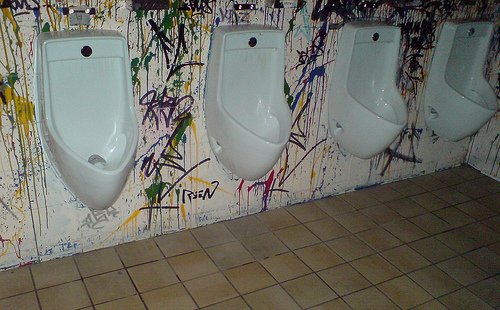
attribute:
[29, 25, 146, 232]
bathroom urinal — white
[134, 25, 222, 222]
graffiti — colorful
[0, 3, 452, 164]
bathroom walls — vandalized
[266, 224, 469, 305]
tile floor — beige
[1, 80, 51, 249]
smearing paint — yellow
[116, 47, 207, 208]
scribble — black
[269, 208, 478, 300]
shapes — square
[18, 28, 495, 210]
urinals — four  white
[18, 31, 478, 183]
wall — dirty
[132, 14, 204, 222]
paint — green dripping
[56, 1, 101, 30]
sheet — metal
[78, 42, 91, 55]
circle — metal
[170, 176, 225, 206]
letters — black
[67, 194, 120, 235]
writing — gray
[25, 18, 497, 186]
urinals — in a row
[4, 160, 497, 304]
tile floor — tan